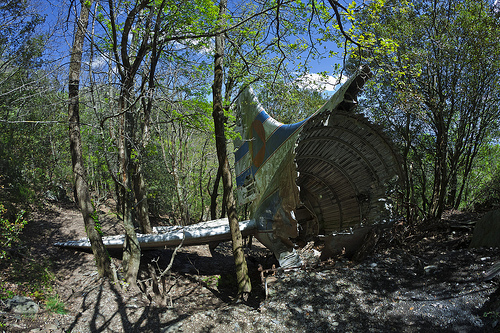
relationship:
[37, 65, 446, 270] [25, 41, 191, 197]
airplane in woods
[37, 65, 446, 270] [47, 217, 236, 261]
airplane has a tail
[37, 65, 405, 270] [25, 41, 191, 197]
airplane in woods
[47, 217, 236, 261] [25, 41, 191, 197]
tail in woods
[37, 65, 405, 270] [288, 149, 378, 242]
airplane has crashed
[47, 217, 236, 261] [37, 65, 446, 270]
tail of an airplane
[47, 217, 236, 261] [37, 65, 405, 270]
tail of a airplane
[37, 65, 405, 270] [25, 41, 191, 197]
airplane crashed in woods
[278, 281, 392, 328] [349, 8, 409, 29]
ground has leaves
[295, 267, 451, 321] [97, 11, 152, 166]
shadow of a tree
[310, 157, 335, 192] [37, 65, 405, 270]
inside of a airplane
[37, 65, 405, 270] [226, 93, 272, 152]
airplane has a wing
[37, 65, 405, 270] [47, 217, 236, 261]
airplane has a tail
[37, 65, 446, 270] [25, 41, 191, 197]
airplane crashed in woods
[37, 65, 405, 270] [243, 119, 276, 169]
airplane has a drawing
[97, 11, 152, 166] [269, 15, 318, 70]
tree has thin branches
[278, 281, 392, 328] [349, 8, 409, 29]
ground has no leaves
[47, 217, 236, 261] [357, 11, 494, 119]
tail between trees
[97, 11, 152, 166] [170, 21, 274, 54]
tree has branches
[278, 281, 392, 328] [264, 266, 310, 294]
ground has dirt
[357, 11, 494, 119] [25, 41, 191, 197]
trees in woods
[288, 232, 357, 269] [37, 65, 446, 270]
crash of an airplane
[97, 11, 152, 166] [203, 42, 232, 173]
tree has long trunks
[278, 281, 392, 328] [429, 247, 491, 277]
ground has rocks